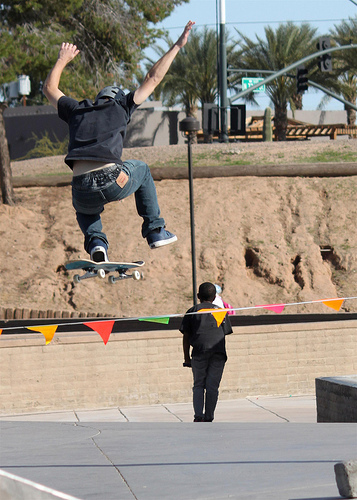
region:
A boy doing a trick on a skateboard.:
[42, 20, 197, 264]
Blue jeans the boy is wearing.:
[70, 161, 177, 263]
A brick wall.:
[1, 319, 356, 409]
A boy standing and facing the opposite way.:
[181, 281, 234, 423]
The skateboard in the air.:
[63, 257, 145, 282]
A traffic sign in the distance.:
[239, 76, 266, 93]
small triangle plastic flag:
[24, 324, 57, 345]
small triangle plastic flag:
[82, 320, 115, 343]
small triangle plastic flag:
[137, 315, 169, 327]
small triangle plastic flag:
[197, 308, 227, 326]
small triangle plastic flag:
[257, 303, 286, 315]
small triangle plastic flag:
[314, 298, 346, 311]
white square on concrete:
[75, 406, 123, 417]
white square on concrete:
[122, 409, 174, 415]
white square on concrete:
[127, 416, 180, 420]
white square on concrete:
[180, 415, 286, 421]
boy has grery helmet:
[81, 79, 150, 101]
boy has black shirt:
[65, 77, 154, 168]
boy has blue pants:
[65, 169, 167, 248]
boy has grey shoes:
[115, 229, 192, 263]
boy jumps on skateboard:
[47, 239, 150, 287]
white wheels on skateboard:
[47, 258, 146, 294]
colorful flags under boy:
[8, 282, 332, 349]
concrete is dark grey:
[13, 407, 203, 473]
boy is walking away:
[157, 304, 243, 411]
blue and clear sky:
[267, 1, 310, 27]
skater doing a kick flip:
[42, 18, 197, 259]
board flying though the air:
[62, 256, 146, 282]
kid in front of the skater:
[180, 282, 233, 426]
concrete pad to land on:
[3, 420, 351, 498]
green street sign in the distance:
[238, 76, 270, 95]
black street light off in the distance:
[315, 34, 334, 73]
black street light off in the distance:
[292, 59, 308, 94]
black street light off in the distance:
[228, 100, 245, 135]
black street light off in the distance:
[201, 99, 219, 133]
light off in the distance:
[180, 112, 203, 311]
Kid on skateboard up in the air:
[45, 19, 194, 282]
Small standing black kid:
[178, 281, 231, 421]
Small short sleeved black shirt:
[180, 303, 233, 364]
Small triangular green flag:
[137, 315, 169, 332]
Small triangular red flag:
[84, 320, 116, 346]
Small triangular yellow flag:
[26, 321, 59, 342]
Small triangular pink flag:
[257, 301, 287, 315]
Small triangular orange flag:
[323, 296, 346, 315]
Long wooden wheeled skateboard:
[63, 257, 145, 286]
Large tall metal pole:
[217, 0, 227, 143]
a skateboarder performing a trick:
[41, 20, 198, 281]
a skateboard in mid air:
[62, 258, 145, 282]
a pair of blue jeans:
[70, 159, 164, 253]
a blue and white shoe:
[147, 226, 177, 249]